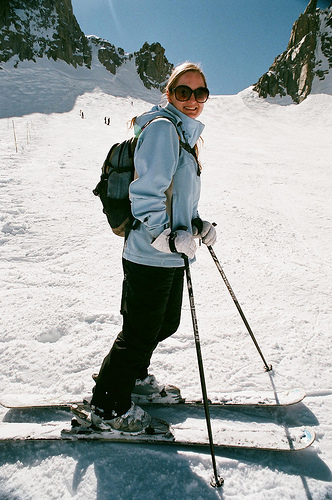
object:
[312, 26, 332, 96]
snow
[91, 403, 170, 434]
foot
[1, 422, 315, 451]
ski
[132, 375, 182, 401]
foot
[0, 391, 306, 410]
ski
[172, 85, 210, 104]
shades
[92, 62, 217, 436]
woman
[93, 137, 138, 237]
backpack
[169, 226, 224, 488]
ski pole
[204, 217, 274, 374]
ski pole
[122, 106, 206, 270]
jacket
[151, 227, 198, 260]
glove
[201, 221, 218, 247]
glove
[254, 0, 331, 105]
mountains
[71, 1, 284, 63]
sky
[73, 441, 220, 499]
shadow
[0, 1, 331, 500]
landscape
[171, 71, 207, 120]
face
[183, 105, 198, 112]
mouth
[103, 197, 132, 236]
part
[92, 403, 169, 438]
snow boot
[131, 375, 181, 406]
snow boot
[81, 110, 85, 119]
skiers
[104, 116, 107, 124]
skiers